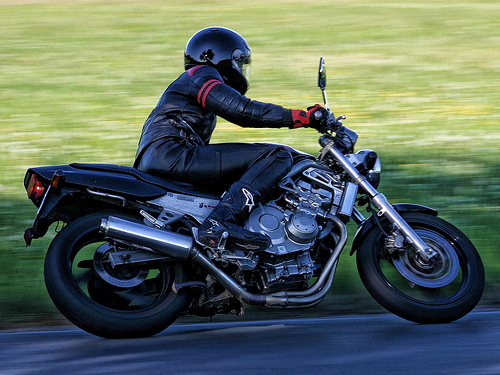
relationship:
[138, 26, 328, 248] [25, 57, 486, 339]
person riding motorcycle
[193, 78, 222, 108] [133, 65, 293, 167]
stripes sewn on jacket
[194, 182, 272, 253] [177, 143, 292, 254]
boot worn on leg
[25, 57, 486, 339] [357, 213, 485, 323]
motorcycle has front wheel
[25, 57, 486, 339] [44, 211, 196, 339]
motorcycle has rear wheel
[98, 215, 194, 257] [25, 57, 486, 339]
muffler attached to motorcycle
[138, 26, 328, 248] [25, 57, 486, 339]
person turning motorcycle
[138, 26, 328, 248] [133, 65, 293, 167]
person wearing jacket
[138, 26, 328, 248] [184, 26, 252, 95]
person wearing helmet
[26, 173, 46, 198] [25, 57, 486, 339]
tail light attached to motorcycle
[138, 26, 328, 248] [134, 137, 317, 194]
person wearing pants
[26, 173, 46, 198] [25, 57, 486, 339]
tail light mounted on motorcycle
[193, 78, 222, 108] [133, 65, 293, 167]
stripes located on jacket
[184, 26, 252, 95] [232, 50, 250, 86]
helmet has visor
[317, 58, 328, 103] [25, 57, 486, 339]
rearview mirror attached to motorcycle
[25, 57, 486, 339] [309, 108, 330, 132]
motorcycle has handlebar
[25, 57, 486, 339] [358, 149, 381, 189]
motorcycle has headlight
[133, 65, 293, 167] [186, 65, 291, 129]
jacket has sleeve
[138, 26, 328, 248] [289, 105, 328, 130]
person wearing glove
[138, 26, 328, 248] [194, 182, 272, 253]
person wearing boot